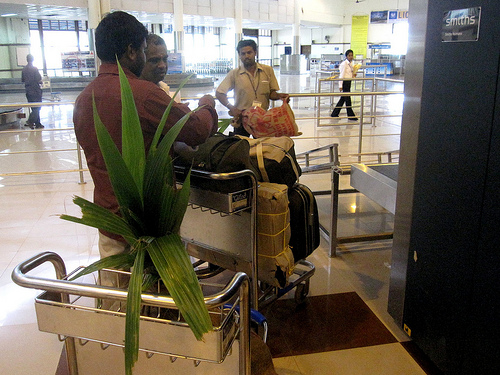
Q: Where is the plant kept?
A: On the luggage kart.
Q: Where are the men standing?
A: At the airport.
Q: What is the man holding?
A: A bag.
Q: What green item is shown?
A: A plant.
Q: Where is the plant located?
A: In a basket.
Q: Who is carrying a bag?
A: A man.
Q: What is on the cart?
A: Luggage.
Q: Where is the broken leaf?
A: Near the bottom of the plant, on the left side.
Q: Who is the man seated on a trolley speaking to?
A: A bearded man, in a long-sleeved, brown shirt.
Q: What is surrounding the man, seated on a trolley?
A: Pieces of luggage.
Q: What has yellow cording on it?
A: A large package, covered in brown paper.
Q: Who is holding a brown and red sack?
A: A man in a tan, uniform top and lanyard.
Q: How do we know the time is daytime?
A: The interior has large windows, facing front, letting in lots of sunlight.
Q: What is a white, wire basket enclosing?
A: A plant.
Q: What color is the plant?
A: Green.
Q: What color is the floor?
A: White and brown.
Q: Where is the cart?
A: On the ground.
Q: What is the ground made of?
A: Tile.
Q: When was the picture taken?
A: Daytime.